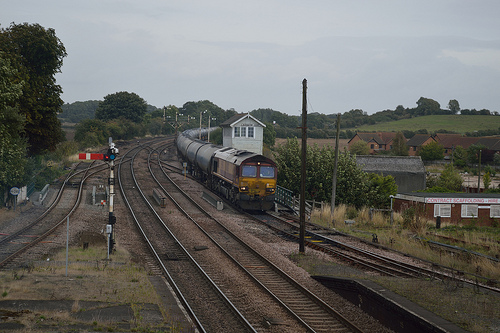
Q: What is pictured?
A: A train next to a little town.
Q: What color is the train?
A: Yellow and black.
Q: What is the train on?
A: Train tracks.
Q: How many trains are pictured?
A: Just 1.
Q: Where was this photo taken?
A: By a set of tracks.